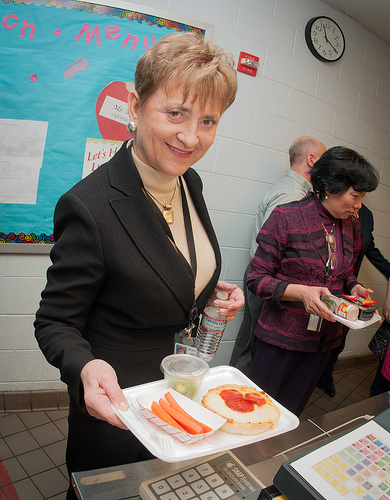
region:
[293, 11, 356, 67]
round wall clock on a white wall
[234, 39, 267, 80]
red fire alarm on a wall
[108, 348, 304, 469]
cafeteria lunch tray with food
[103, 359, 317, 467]
lunch tray with carrots and pizza bread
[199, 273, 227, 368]
bottle of water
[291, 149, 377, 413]
lady getting her lunch in a cafeteria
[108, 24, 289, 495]
lady with short hair carrying a cafeteria tray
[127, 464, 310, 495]
cash register in a cafeteria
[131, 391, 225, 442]
paper boat of carrot sticks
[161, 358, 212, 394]
plastic cup full of kiwi slices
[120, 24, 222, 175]
A happy hungry woman.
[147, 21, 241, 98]
A short hairstyle.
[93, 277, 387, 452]
Trays of food to eat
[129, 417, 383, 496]
Buttons for ringing up sales.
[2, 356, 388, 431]
Tile flooring.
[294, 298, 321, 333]
An ID badge.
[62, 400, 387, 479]
A metal counter for the cash register to rest upon.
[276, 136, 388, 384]
More people waiting in line to purchase their food.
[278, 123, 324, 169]
Balding man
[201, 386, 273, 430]
Personal pizza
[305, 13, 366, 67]
clock on the wall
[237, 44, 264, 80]
red fire alarm device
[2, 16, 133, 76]
words on bulletin board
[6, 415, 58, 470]
part of tiled floor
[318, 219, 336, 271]
a necklace worn by lady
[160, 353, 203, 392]
clear container with food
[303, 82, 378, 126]
portion of white wall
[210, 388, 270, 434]
pepperoni and cheese pizza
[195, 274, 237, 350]
bottle of water in hand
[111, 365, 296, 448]
white tray with food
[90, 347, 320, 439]
A full lunch tray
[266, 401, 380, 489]
A register for ringing up food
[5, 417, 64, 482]
A tile floor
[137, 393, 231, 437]
Carrot sticks in a paper basket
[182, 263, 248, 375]
A woman holding a water bottle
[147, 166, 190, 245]
A woman wearing a gold pendant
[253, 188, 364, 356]
A woman in a purple and black jacket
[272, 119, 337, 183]
A balding man's head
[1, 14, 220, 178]
A decorated board behind a woman's head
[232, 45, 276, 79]
A fire alarm on a tile wall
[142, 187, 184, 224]
a gold necklace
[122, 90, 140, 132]
earring on woman's ear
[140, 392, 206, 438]
carrots in container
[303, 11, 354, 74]
a clock on wall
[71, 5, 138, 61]
words on bulletin board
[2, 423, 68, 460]
part of tile floor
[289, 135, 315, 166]
back of balding man's head and ear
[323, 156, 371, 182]
portion of black hair